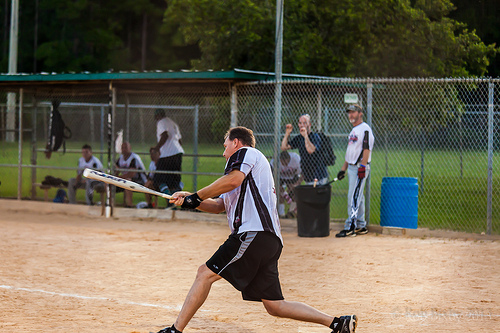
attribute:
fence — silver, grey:
[395, 74, 499, 221]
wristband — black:
[178, 191, 201, 211]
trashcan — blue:
[381, 176, 421, 229]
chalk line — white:
[0, 275, 196, 322]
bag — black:
[48, 101, 67, 153]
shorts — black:
[206, 227, 284, 303]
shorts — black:
[150, 153, 184, 186]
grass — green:
[2, 138, 499, 236]